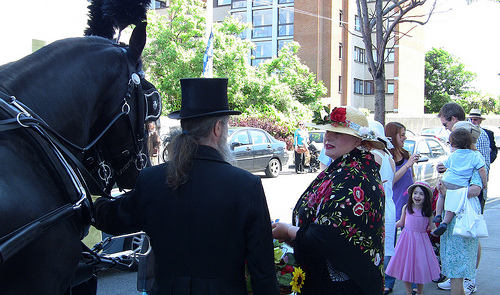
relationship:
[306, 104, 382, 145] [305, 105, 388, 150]
flower on cover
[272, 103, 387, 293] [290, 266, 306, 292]
woman near sunflower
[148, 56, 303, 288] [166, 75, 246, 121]
man wearing hat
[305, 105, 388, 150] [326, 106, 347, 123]
cover with a flower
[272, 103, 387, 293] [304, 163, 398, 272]
woman wearing a shawl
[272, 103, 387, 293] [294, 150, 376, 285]
woman has jacket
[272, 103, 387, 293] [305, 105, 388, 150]
woman wearing cover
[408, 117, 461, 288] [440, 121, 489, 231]
woman holding child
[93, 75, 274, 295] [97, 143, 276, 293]
man has jacket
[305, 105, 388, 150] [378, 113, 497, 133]
cover on fence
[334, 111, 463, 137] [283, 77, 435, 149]
cover on fence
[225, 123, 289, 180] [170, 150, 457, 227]
car on side of street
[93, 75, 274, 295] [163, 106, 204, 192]
man with hair